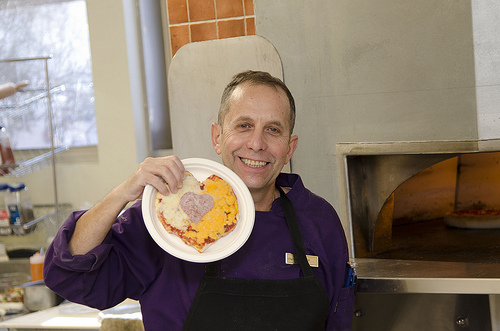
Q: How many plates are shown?
A: One.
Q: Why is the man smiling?
A: He is posing for a picture.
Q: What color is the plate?
A: White.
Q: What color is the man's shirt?
A: Purple.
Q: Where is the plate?
A: In the man's hand.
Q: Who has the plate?
A: The man.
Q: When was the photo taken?
A: Daytime.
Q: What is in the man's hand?
A: The plate.